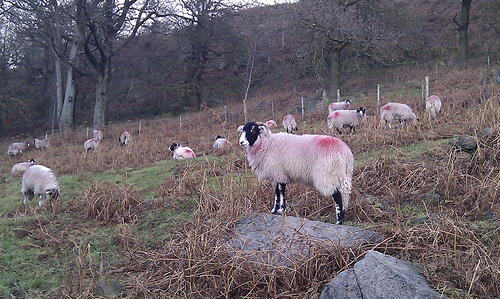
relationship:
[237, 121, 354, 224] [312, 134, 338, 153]
sheep have marking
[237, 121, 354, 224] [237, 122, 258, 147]
sheep has face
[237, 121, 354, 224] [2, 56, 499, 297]
sheep on hill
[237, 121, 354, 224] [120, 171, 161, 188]
sheep eating grass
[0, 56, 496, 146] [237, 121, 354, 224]
fence behind sheep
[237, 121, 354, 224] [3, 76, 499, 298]
sheep in field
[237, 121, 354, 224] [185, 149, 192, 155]
sheep have paint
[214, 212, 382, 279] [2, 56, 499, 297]
rock on hill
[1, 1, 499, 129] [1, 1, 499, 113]
trees in background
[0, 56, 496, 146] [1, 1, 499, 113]
fence in background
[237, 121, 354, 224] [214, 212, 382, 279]
sheep on rock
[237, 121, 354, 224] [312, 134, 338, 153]
sheep has marking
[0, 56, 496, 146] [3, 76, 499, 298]
fence in field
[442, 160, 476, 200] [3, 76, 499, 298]
straw in field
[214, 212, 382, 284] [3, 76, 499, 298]
rock in field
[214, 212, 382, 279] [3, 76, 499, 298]
rock in field